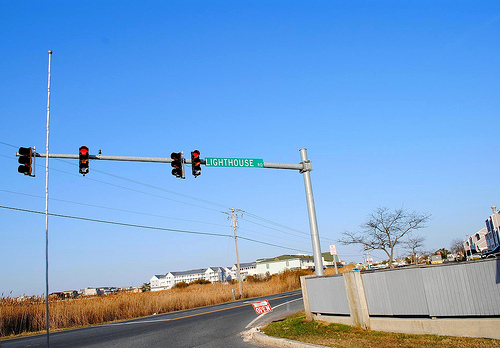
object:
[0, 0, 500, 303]
sky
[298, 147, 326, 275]
pole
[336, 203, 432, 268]
tree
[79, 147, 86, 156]
red light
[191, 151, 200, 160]
red light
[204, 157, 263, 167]
sign